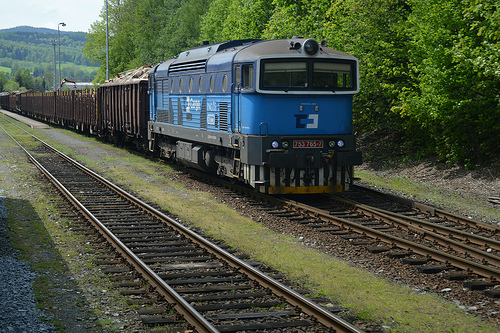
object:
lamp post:
[57, 21, 67, 92]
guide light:
[302, 38, 321, 56]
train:
[0, 35, 363, 197]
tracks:
[316, 214, 367, 230]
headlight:
[271, 139, 280, 148]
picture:
[0, 0, 500, 331]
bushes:
[388, 0, 500, 168]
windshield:
[260, 59, 356, 91]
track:
[33, 137, 364, 333]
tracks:
[367, 210, 500, 266]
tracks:
[172, 294, 221, 332]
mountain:
[0, 24, 99, 93]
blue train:
[145, 34, 364, 195]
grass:
[0, 110, 500, 333]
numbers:
[306, 141, 310, 146]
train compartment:
[73, 87, 99, 136]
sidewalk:
[0, 133, 103, 333]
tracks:
[47, 177, 99, 226]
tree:
[387, 0, 483, 173]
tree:
[321, 0, 412, 147]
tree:
[259, 0, 334, 40]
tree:
[219, 0, 278, 42]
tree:
[195, 0, 233, 46]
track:
[279, 197, 500, 282]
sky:
[0, 0, 107, 35]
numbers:
[298, 141, 302, 146]